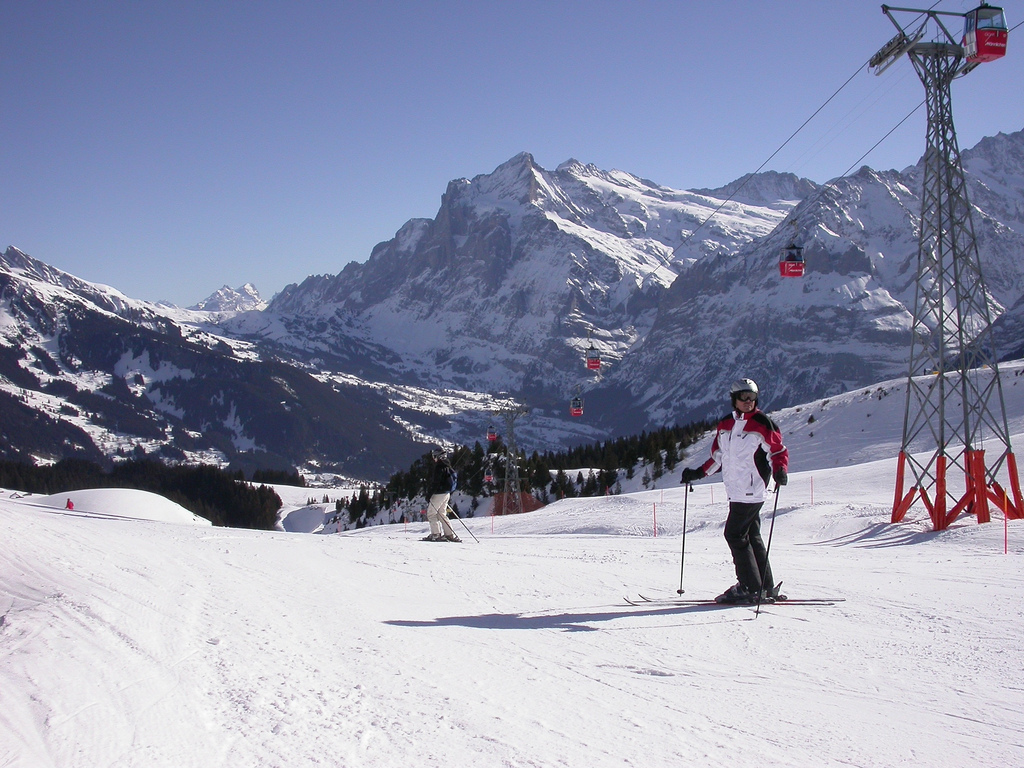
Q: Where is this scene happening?
A: On a ski slope.